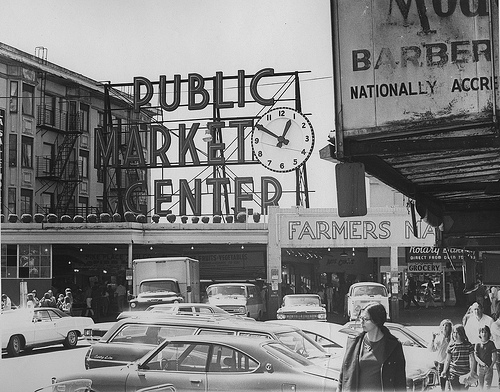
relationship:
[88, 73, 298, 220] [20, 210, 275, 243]
sign above roof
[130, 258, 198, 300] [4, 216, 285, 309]
truck by market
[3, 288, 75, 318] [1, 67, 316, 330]
people in front of market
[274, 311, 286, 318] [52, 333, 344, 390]
headlights on car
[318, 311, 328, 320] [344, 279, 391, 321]
headlights on car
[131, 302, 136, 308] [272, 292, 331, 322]
headlights on car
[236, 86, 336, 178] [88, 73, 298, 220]
clock on sign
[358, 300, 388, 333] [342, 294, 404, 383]
head on person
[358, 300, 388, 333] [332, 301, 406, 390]
head on person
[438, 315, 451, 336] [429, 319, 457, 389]
head on person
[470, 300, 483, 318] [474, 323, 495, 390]
head on child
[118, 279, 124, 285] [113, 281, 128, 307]
head on person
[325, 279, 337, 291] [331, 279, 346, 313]
head on person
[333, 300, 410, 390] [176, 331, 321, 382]
woman walking near car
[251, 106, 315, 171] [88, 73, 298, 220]
clock on sign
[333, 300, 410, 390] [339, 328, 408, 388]
woman wearing jacket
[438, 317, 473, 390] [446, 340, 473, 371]
girl wearing a shirt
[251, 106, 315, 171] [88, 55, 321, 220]
clock on sign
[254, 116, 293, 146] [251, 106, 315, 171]
black hands on clock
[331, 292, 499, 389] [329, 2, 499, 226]
people at market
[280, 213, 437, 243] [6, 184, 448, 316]
sign at market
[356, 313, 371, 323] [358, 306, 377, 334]
glasses on face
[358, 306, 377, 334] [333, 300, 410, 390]
face on woman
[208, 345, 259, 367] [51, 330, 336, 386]
window on car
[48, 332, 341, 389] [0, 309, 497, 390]
vehicle on road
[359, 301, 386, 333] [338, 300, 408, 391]
head on person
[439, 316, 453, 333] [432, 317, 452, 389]
head on child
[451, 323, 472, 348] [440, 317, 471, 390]
head on girl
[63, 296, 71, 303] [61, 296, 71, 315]
head on person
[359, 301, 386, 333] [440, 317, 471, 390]
head on girl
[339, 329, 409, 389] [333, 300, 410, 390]
coat on woman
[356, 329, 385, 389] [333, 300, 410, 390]
shirt on woman